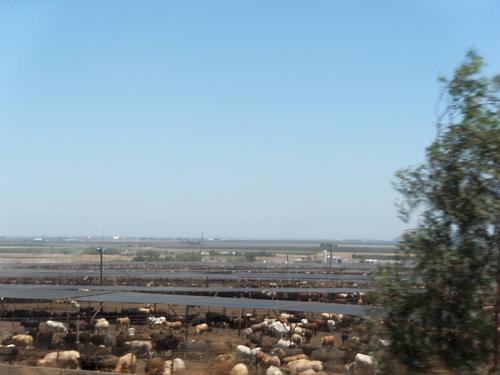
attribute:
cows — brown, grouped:
[6, 293, 397, 375]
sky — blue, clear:
[1, 3, 499, 240]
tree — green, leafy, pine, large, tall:
[385, 53, 499, 372]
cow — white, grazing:
[47, 320, 70, 339]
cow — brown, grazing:
[144, 358, 164, 375]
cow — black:
[156, 332, 181, 356]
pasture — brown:
[4, 249, 499, 374]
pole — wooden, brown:
[93, 248, 107, 283]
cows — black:
[9, 299, 231, 328]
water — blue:
[10, 282, 392, 321]